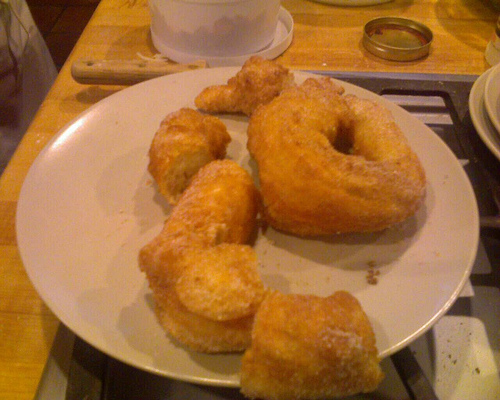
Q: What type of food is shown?
A: Doughnuts.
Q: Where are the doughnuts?
A: Plate.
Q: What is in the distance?
A: Plastic container.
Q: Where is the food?
A: On the plate.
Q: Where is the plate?
A: Under the food.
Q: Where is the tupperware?
A: Behind the plate.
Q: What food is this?
A: Donuts.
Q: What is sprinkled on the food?
A: Sugar.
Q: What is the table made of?
A: Wood.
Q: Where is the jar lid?
A: On the table.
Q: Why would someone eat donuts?
A: Nourishment.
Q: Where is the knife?
A: Next to the plate.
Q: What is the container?
A: A plate.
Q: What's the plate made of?
A: Plastic.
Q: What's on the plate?
A: Donuts.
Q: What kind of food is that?
A: Donut hole.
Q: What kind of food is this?
A: Part of a donut.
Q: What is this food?
A: A donut.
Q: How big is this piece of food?
A: It's small.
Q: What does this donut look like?
A: A chicken wing.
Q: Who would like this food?
A: A donut-eater.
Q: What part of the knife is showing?
A: The wooden handle.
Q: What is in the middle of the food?
A: A hole.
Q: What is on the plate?
A: A donut.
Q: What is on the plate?
A: Donut pieces.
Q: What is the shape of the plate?
A: Round.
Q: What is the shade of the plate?
A: White.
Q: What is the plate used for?
A: Donuts.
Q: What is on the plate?
A: Various donuts.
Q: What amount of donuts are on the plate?
A: Five pieces.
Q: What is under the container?
A: A lid.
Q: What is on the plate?
A: Donuts.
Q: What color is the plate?
A: White.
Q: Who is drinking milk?
A: No one.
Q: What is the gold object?
A: A lid.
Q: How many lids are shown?
A: Two.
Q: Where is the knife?
A: Beside the plate.